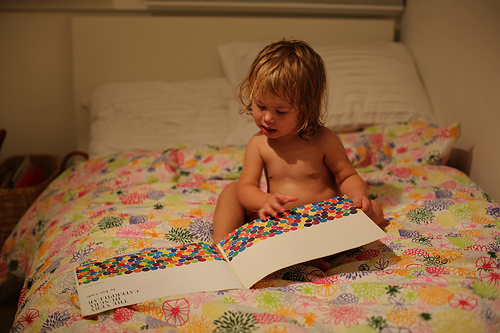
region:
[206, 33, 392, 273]
a child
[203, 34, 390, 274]
a naked child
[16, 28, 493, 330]
the child is on a bed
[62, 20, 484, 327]
a child sitting on a bed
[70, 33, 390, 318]
the child reads a book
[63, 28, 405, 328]
the child is looking at a book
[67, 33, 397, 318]
a book is open in front of the child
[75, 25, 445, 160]
two white pillows behind the child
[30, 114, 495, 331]
the bedspread is white with colorful patterns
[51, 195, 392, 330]
the book has lots of colored circles on it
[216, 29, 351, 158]
a young child with blonde hair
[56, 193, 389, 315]
a book with colorful dots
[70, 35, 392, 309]
a child looking at a book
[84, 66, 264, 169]
white striped pillow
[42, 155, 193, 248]
a flower blankent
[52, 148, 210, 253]
comforter with many colors of flowers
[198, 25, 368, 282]
child looking at a book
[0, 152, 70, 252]
wicker basket that holds books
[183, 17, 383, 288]
a child entranced in a book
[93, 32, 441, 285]
child reading before bedtime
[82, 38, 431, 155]
two pillows propped up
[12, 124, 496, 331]
colored bed spread on bed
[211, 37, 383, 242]
shirtless child on bed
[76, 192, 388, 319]
open pages of book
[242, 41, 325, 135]
light brown hair on head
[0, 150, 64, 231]
wicker basket next to bed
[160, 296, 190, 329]
red flower on bread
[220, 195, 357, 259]
colored circles on page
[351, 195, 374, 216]
child's hand holding page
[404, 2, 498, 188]
tan wall of bedroom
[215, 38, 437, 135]
white pillow on the bed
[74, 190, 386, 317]
large children's book with a lot of colors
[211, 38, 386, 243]
small child reading a book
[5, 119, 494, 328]
colorful bed spread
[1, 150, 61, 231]
brown wicker basket by the bed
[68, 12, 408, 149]
white panel part of wall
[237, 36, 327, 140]
blonde wet hair on the child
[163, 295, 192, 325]
round red design on the blanket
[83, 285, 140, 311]
black words on the book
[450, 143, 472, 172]
small shadow on the wall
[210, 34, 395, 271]
A little naked child with blonde hair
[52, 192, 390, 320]
A picture book opened to a colorful page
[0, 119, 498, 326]
A colorful bedspread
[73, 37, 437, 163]
Two white pillows, side by side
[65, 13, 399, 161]
A white headboard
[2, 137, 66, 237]
A basket beside the bed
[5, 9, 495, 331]
A bed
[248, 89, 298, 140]
An intent look upon the child's face as the child regards the picture book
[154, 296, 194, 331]
A stylized red flower on the comforter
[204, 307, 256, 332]
A stylized green flower on the comforter